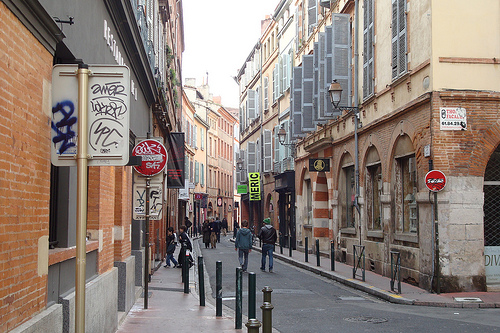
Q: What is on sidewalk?
A: Poles.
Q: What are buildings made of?
A: Brick.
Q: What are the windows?
A: Arched.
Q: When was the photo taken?
A: Daytime.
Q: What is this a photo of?
A: An urban street.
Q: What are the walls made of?
A: Bricks.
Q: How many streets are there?
A: One.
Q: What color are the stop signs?
A: Red.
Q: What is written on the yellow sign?
A: Meric.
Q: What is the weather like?
A: Sunny.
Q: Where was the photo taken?
A: City sidewalk.